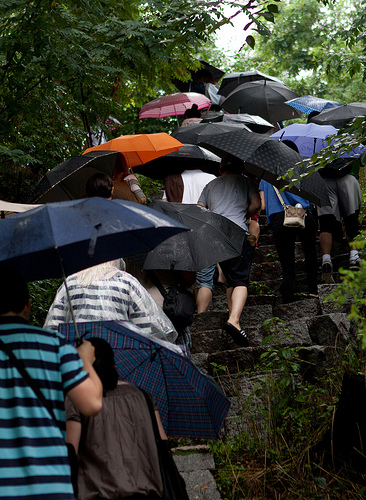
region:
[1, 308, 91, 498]
Man is wearing a shirt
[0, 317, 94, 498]
Man wearing a blue and black shirt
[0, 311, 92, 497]
Man is wearing a blue and black shirt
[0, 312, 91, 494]
Man wearing a striped shirt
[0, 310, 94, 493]
Man is wearing a striped shirt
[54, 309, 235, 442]
Woman holding an umbrella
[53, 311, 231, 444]
Woman is holding an umbrella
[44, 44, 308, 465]
people walking outside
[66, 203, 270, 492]
people walking in the rain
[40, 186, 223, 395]
people holding open umbrellas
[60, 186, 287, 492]
open umbrellas that are outside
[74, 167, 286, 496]
stairs with people walk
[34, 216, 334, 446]
wet stairs from rain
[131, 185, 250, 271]
a black open umbrella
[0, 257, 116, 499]
a man in a blue and black stripe shirt.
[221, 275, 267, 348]
a woman wearing a shoe.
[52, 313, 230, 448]
a blue and gray umbrella.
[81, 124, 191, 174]
an orange umbrella.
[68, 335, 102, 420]
the right arm of a man.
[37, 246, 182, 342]
a woman wearing a rain coat.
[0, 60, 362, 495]
a crowd of people walking up some steps.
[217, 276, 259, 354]
a right leg on a woman.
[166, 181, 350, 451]
steps leading to location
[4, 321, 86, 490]
shirt on the person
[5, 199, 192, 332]
umbrella held by person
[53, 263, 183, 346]
clear coat for rain protection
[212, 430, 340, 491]
green and brown grass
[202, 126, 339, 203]
black umbrella held by person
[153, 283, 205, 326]
bag on person's shoulder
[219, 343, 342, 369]
step made of stone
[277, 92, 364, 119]
blue umbrella carried by person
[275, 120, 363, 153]
light blue umbrella held by person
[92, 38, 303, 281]
people walking up the stairs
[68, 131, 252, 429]
people walking in the rain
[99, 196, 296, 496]
people walking up stairs in the rain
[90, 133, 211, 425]
people walking and holding umrbellas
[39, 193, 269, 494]
open wet umbrellas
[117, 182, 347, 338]
an open black umbrella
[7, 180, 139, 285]
an open blue umbrella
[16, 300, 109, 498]
a blue striped shirt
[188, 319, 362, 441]
green grass next to stairs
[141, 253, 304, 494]
stairs made of cement